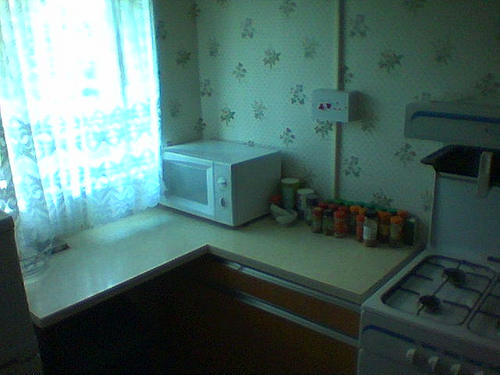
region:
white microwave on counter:
[155, 138, 282, 227]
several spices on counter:
[271, 175, 421, 249]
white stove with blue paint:
[354, 99, 499, 373]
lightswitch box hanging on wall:
[312, 88, 353, 126]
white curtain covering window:
[0, 0, 166, 250]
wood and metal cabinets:
[210, 255, 364, 374]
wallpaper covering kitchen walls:
[151, 3, 496, 235]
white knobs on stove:
[402, 344, 465, 374]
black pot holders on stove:
[378, 252, 498, 342]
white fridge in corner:
[1, 206, 45, 373]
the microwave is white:
[166, 147, 284, 227]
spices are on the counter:
[261, 174, 421, 247]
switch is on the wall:
[306, 86, 361, 123]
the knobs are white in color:
[393, 341, 474, 368]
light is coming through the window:
[15, 27, 141, 151]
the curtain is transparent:
[25, 25, 175, 198]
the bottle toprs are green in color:
[332, 192, 387, 211]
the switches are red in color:
[302, 94, 347, 119]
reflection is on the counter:
[68, 223, 169, 288]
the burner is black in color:
[410, 256, 480, 323]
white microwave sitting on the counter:
[162, 116, 264, 236]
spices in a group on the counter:
[316, 202, 408, 254]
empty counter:
[73, 228, 213, 273]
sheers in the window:
[14, 29, 151, 219]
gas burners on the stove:
[416, 256, 478, 340]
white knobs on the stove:
[396, 340, 453, 372]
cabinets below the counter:
[230, 280, 314, 371]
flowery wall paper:
[213, 54, 291, 139]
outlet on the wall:
[305, 83, 358, 131]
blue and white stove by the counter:
[385, 108, 497, 337]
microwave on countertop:
[153, 126, 285, 230]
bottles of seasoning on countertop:
[268, 171, 423, 251]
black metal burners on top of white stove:
[375, 244, 494, 329]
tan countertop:
[7, 195, 428, 340]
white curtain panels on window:
[0, 42, 175, 264]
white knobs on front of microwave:
[206, 170, 235, 217]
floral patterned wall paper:
[202, 51, 302, 141]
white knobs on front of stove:
[401, 335, 498, 372]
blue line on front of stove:
[362, 318, 484, 374]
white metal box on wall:
[305, 78, 364, 133]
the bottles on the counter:
[266, 175, 410, 247]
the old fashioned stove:
[355, 147, 497, 372]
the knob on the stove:
[404, 348, 420, 365]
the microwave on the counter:
[156, 136, 283, 227]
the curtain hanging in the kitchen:
[0, 0, 167, 274]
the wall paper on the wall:
[152, 0, 497, 243]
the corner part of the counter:
[22, 167, 427, 329]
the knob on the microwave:
[216, 175, 226, 190]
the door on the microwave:
[157, 150, 215, 221]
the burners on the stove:
[380, 253, 499, 340]